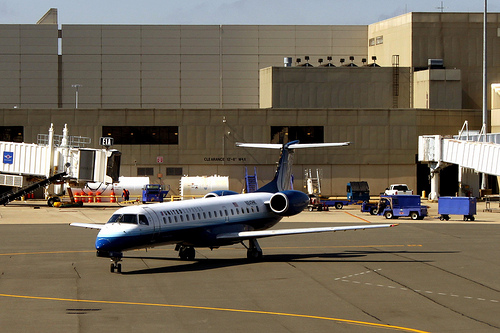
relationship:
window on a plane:
[201, 209, 207, 220] [65, 128, 402, 278]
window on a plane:
[230, 205, 241, 222] [60, 114, 405, 282]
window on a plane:
[178, 197, 238, 219] [56, 127, 384, 302]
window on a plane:
[252, 202, 263, 216] [91, 126, 353, 271]